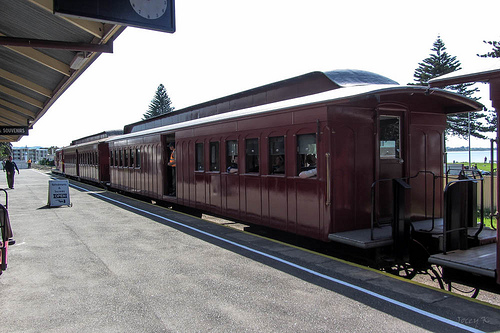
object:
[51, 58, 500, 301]
train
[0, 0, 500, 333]
station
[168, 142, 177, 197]
man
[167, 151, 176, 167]
vest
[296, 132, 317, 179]
window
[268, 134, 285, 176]
window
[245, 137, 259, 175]
window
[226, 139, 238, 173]
window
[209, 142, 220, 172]
window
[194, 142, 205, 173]
window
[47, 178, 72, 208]
sign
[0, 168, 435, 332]
ground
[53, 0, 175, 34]
clock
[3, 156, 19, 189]
man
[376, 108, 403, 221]
door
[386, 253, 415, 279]
wheel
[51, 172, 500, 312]
line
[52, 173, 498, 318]
curb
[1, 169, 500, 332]
sidewalk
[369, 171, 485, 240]
rail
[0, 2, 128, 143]
awning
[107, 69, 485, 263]
car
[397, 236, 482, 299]
cable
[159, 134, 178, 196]
door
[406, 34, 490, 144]
tree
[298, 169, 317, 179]
arm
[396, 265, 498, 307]
tracks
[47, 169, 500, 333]
shadow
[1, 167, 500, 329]
pavement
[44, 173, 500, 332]
paint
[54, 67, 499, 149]
roof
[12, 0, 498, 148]
sky